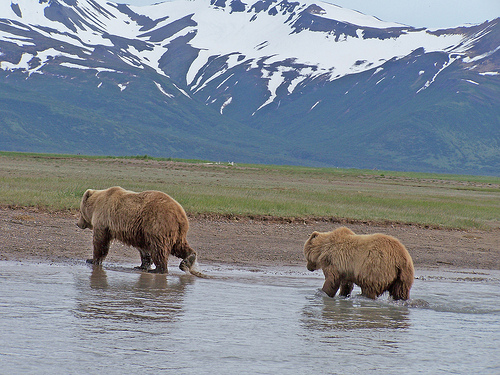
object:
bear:
[70, 182, 198, 278]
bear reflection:
[72, 268, 193, 338]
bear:
[301, 226, 415, 306]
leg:
[150, 240, 169, 270]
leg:
[172, 234, 196, 259]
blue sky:
[325, 0, 499, 28]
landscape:
[1, 0, 497, 314]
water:
[2, 257, 496, 374]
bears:
[75, 183, 198, 275]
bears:
[73, 175, 198, 276]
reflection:
[300, 291, 411, 339]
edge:
[0, 192, 461, 232]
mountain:
[2, 2, 499, 162]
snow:
[1, 0, 497, 108]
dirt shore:
[0, 212, 497, 266]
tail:
[170, 218, 189, 257]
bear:
[66, 144, 252, 331]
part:
[232, 309, 331, 363]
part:
[135, 310, 212, 348]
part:
[151, 245, 167, 257]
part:
[300, 168, 370, 221]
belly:
[344, 276, 367, 286]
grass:
[0, 149, 499, 233]